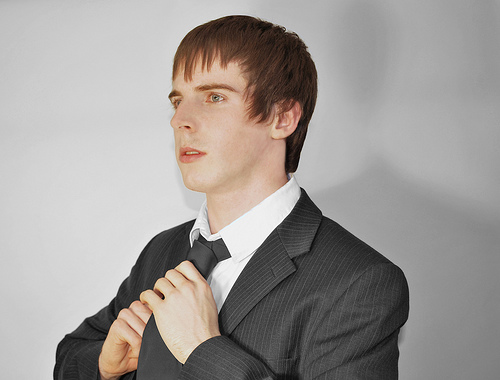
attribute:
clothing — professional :
[52, 175, 410, 378]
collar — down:
[182, 200, 294, 267]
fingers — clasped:
[116, 250, 198, 357]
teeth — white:
[184, 151, 195, 153]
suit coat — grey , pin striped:
[54, 185, 409, 378]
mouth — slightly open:
[168, 148, 205, 161]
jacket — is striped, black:
[31, 198, 406, 378]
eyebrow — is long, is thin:
[198, 85, 247, 97]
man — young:
[50, 7, 481, 365]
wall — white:
[17, 14, 498, 371]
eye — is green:
[204, 90, 229, 106]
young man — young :
[46, 13, 408, 375]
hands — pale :
[99, 259, 222, 379]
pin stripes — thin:
[282, 236, 406, 373]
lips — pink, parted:
[177, 144, 207, 165]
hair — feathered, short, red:
[170, 14, 317, 174]